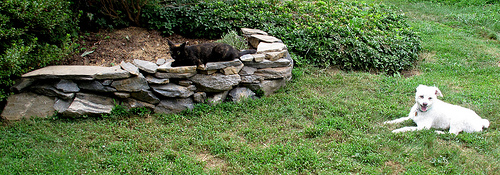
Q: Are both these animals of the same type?
A: No, they are dogs and cats.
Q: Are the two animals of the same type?
A: No, they are dogs and cats.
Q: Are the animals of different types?
A: Yes, they are dogs and cats.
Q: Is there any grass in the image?
A: Yes, there is grass.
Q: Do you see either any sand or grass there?
A: Yes, there is grass.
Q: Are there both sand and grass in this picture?
A: No, there is grass but no sand.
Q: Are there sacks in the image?
A: No, there are no sacks.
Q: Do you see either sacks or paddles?
A: No, there are no sacks or paddles.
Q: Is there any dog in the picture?
A: Yes, there is a dog.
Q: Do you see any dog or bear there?
A: Yes, there is a dog.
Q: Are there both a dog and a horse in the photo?
A: No, there is a dog but no horses.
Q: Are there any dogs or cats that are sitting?
A: Yes, the dog is sitting.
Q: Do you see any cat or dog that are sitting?
A: Yes, the dog is sitting.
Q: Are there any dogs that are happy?
A: Yes, there is a happy dog.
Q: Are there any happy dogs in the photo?
A: Yes, there is a happy dog.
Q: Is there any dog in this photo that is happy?
A: Yes, there is a dog that is happy.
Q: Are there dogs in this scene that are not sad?
A: Yes, there is a happy dog.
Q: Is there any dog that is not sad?
A: Yes, there is a happy dog.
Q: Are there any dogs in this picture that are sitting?
A: Yes, there is a dog that is sitting.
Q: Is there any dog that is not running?
A: Yes, there is a dog that is sitting.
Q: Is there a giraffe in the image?
A: No, there are no giraffes.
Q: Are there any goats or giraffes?
A: No, there are no giraffes or goats.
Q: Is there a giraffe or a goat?
A: No, there are no giraffes or goats.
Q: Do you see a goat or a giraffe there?
A: No, there are no giraffes or goats.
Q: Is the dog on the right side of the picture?
A: Yes, the dog is on the right of the image.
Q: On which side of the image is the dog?
A: The dog is on the right of the image.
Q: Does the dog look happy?
A: Yes, the dog is happy.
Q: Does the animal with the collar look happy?
A: Yes, the dog is happy.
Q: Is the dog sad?
A: No, the dog is happy.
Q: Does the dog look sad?
A: No, the dog is happy.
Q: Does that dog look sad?
A: No, the dog is happy.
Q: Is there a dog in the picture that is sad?
A: No, there is a dog but it is happy.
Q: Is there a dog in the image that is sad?
A: No, there is a dog but it is happy.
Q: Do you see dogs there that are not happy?
A: No, there is a dog but it is happy.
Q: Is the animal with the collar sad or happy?
A: The dog is happy.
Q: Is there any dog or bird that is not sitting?
A: No, there is a dog but it is sitting.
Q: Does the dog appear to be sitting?
A: Yes, the dog is sitting.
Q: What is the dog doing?
A: The dog is sitting.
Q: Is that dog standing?
A: No, the dog is sitting.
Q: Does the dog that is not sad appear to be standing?
A: No, the dog is sitting.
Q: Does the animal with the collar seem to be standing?
A: No, the dog is sitting.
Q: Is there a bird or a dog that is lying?
A: No, there is a dog but it is sitting.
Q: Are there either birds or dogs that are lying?
A: No, there is a dog but it is sitting.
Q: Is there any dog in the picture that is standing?
A: No, there is a dog but it is sitting.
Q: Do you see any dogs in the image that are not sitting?
A: No, there is a dog but it is sitting.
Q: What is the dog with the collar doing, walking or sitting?
A: The dog is sitting.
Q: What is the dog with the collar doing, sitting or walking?
A: The dog is sitting.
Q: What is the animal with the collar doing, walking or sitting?
A: The dog is sitting.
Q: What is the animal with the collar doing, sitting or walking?
A: The dog is sitting.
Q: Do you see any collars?
A: Yes, there is a collar.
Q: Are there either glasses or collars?
A: Yes, there is a collar.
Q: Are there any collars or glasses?
A: Yes, there is a collar.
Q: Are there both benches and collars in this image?
A: No, there is a collar but no benches.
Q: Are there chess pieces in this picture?
A: No, there are no chess pieces.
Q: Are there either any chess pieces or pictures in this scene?
A: No, there are no chess pieces or pictures.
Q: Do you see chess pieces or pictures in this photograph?
A: No, there are no chess pieces or pictures.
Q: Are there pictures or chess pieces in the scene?
A: No, there are no chess pieces or pictures.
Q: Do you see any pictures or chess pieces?
A: No, there are no chess pieces or pictures.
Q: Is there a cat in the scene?
A: Yes, there is a cat.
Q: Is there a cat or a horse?
A: Yes, there is a cat.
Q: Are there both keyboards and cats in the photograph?
A: No, there is a cat but no keyboards.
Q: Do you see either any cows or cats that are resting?
A: Yes, the cat is resting.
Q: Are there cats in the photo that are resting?
A: Yes, there is a cat that is resting.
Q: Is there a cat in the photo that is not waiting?
A: Yes, there is a cat that is resting.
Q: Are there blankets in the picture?
A: No, there are no blankets.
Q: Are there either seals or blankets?
A: No, there are no blankets or seals.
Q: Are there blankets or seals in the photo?
A: No, there are no blankets or seals.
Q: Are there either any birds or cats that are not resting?
A: No, there is a cat but it is resting.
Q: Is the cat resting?
A: Yes, the cat is resting.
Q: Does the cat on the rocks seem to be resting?
A: Yes, the cat is resting.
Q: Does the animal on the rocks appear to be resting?
A: Yes, the cat is resting.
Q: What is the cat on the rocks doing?
A: The cat is resting.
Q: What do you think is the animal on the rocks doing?
A: The cat is resting.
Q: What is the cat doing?
A: The cat is resting.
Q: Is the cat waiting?
A: No, the cat is resting.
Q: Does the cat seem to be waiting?
A: No, the cat is resting.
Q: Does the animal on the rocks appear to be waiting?
A: No, the cat is resting.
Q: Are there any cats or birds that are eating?
A: No, there is a cat but it is resting.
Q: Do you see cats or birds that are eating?
A: No, there is a cat but it is resting.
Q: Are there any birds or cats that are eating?
A: No, there is a cat but it is resting.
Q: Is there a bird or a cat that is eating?
A: No, there is a cat but it is resting.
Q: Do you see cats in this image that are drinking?
A: No, there is a cat but it is resting.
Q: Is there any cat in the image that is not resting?
A: No, there is a cat but it is resting.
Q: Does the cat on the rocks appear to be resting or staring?
A: The cat is resting.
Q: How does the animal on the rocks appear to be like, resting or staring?
A: The cat is resting.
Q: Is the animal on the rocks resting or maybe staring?
A: The cat is resting.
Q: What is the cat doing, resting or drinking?
A: The cat is resting.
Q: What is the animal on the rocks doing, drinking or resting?
A: The cat is resting.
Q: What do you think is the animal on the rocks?
A: The animal is a cat.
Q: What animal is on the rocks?
A: The animal is a cat.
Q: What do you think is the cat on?
A: The cat is on the rocks.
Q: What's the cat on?
A: The cat is on the rocks.